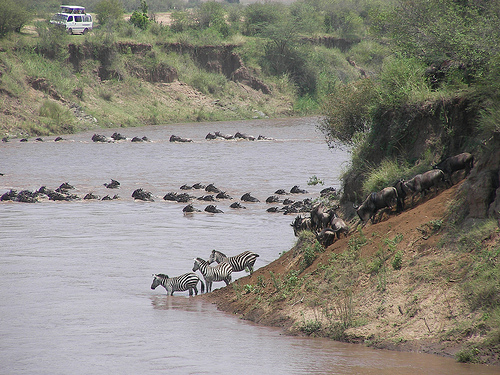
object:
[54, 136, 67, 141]
animals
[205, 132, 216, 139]
buffalo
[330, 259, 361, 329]
plants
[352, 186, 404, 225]
water buffalo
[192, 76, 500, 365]
hill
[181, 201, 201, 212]
buffalo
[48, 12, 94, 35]
van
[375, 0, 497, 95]
shrubs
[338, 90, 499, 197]
cliff edge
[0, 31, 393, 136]
cliff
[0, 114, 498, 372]
river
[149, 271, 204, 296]
zebra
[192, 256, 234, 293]
zebra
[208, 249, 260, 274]
zebra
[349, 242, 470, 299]
grass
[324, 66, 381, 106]
leaves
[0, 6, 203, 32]
road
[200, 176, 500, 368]
dirt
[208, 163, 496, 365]
ground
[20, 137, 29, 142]
wildbeasts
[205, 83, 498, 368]
shore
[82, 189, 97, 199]
wild beast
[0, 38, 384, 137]
river bank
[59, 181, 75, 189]
animals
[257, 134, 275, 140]
animals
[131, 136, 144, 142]
animals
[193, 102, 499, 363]
hill side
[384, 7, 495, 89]
trees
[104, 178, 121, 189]
wildebeest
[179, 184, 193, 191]
animals